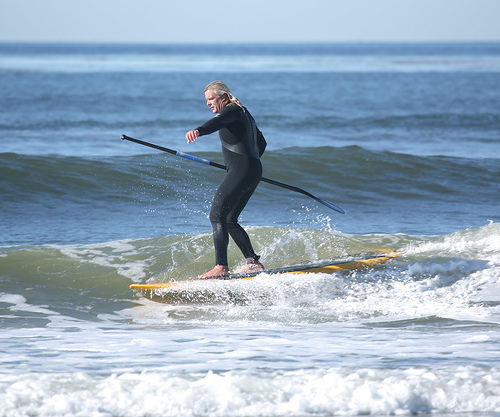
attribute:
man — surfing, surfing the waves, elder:
[186, 81, 268, 278]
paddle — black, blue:
[118, 133, 345, 222]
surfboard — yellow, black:
[124, 249, 404, 297]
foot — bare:
[201, 264, 226, 279]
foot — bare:
[237, 258, 262, 276]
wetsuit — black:
[199, 102, 266, 263]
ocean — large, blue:
[1, 42, 496, 417]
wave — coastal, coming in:
[1, 151, 499, 225]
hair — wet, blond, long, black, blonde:
[204, 81, 243, 112]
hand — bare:
[183, 130, 199, 143]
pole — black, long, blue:
[118, 132, 317, 210]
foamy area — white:
[2, 233, 495, 415]